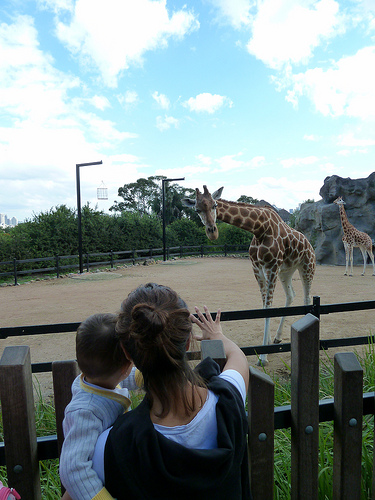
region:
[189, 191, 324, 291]
tall giraffe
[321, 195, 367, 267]
brown girafffe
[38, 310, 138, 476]
baby held by woman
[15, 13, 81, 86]
white clouds in blue sky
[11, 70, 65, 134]
white clouds in blue sky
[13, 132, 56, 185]
white clouds in blue sky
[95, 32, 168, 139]
white clouds in blue sky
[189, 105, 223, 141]
white clouds in blue sky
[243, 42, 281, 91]
white clouds in blue sky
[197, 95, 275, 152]
white clouds in blue sky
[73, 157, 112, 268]
a tall black pole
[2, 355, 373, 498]
a section of green grass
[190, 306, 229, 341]
the hand of a woman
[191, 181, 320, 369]
a tall brown and white giraffe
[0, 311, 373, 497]
part of a wooden fence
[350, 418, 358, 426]
a small fence screw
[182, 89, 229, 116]
a small white cloud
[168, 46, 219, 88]
part of a blue sky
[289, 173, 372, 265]
a tall gray stone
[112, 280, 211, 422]
a woman's dark hair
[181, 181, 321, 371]
a large brown giraffe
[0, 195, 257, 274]
a long section of green trees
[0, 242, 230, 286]
a long black fence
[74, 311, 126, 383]
a boy's short hair cut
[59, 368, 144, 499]
part of a boy's yellow and white sweater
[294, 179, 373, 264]
a large gray rock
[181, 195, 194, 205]
the ear of a giraffe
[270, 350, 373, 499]
a section of green grass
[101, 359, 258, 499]
a woman's black sweater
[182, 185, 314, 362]
giraffe standing on ground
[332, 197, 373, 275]
brown and white giraffe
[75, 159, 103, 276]
black metal pole in ground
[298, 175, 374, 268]
grey stone barrier wall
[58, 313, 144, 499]
boy wearing white sweater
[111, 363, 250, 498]
black cotton sweat shirt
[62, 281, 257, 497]
woman holding child in arm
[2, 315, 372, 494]
black wood picket fence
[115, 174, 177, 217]
tree with green leaves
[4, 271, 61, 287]
grey rocks on ground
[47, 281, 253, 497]
a lady holding a child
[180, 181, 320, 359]
a Griffie in a pen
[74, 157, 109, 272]
a metal pole light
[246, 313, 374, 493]
a wooden fence posts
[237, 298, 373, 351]
a black metal railing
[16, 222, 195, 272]
a line of bushes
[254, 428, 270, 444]
black bolts on a fence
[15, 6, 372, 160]
a blue and white sky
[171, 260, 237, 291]
tan sand on the ground